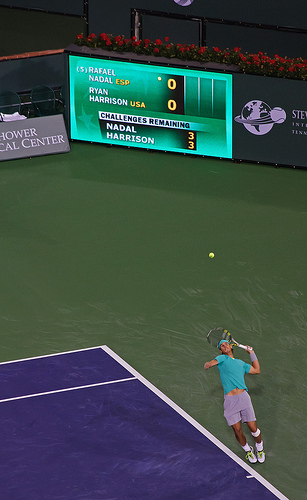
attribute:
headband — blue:
[217, 339, 229, 347]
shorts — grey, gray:
[223, 391, 256, 425]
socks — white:
[242, 441, 263, 452]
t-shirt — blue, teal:
[215, 355, 251, 393]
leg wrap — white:
[251, 428, 261, 438]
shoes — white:
[247, 449, 266, 463]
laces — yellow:
[247, 452, 264, 458]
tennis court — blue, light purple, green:
[1, 345, 288, 500]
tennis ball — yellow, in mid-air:
[208, 252, 214, 257]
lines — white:
[0, 345, 137, 401]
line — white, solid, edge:
[138, 376, 287, 500]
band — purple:
[247, 350, 257, 364]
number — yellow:
[167, 79, 176, 89]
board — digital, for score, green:
[68, 55, 234, 160]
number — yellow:
[167, 100, 175, 111]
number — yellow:
[189, 133, 194, 141]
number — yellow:
[187, 142, 195, 150]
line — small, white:
[1, 378, 140, 403]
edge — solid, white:
[1, 344, 139, 380]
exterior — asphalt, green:
[1, 140, 307, 499]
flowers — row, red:
[76, 32, 307, 79]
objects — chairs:
[1, 86, 67, 120]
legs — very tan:
[232, 421, 261, 446]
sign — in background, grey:
[0, 115, 72, 161]